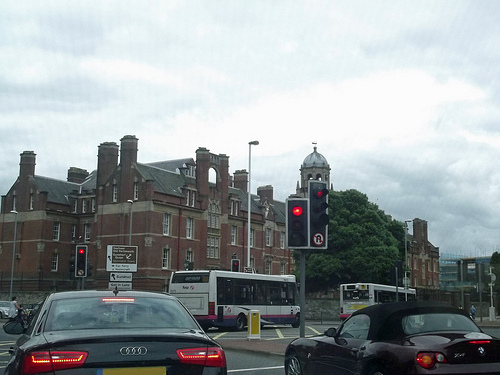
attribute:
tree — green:
[303, 185, 400, 320]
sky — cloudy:
[209, 46, 305, 101]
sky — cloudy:
[230, 65, 351, 121]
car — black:
[262, 290, 474, 373]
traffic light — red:
[287, 197, 310, 247]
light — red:
[291, 190, 317, 232]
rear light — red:
[27, 340, 93, 372]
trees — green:
[293, 186, 398, 288]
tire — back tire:
[238, 310, 251, 328]